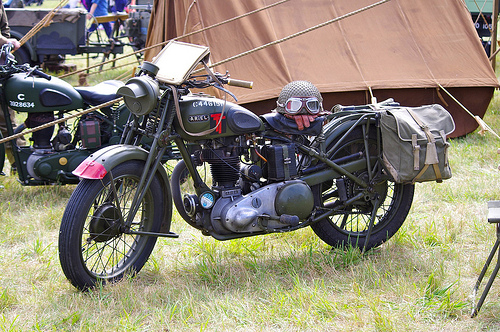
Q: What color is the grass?
A: Green.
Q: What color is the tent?
A: Brown.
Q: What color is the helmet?
A: Gray.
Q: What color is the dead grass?
A: Brown.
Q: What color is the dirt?
A: Brown.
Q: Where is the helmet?
A: On the bike seat.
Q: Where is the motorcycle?
A: On grass.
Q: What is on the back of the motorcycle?
A: Gray bag.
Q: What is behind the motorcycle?
A: Tent.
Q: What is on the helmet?
A: Goggles.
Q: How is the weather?
A: Sunny.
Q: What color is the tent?
A: Brown.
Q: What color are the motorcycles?
A: Black.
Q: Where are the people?
A: Background.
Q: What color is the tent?
A: Brown.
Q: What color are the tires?
A: Black.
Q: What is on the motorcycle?
A: Helmet.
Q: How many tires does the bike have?
A: Two.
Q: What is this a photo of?
A: Motorcycle.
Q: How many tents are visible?
A: 1.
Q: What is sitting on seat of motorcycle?
A: Helmet and glove.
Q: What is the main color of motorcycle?
A: Green.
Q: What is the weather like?
A: Sunny.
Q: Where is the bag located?
A: On motorcycle.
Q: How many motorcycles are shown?
A: 2.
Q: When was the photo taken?
A: Daytime.